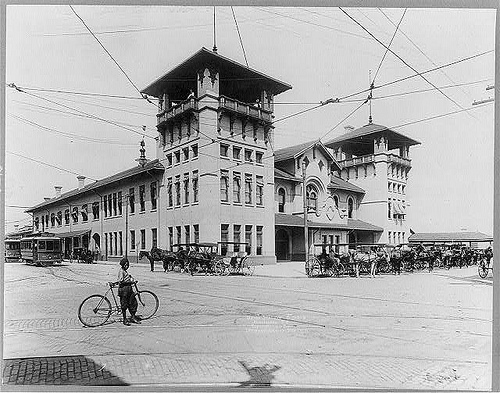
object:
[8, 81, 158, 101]
wire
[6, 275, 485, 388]
street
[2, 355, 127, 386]
shadow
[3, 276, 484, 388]
road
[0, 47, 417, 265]
building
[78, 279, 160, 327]
bicycle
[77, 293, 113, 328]
wheel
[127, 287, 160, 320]
wheel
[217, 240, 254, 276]
horse carriages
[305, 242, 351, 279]
horse carriages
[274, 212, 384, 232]
awning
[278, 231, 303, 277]
doorway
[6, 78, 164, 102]
wires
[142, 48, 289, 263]
building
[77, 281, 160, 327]
bike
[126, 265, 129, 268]
skin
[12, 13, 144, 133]
sky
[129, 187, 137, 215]
windows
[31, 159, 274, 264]
building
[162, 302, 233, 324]
road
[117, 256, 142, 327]
man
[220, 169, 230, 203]
window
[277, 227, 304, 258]
door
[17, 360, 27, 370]
brick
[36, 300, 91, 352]
ground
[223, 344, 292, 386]
ground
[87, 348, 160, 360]
shadow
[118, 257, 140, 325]
woman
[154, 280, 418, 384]
street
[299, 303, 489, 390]
street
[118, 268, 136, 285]
arm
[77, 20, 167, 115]
wire